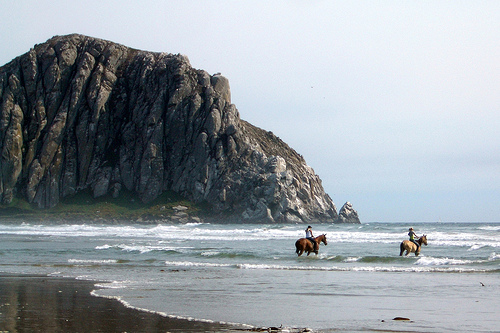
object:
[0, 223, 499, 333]
ocean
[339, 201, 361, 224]
rocks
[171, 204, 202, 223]
rocks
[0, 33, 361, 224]
rocks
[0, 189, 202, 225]
grass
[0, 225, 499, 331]
waves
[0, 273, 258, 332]
sand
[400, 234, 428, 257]
brown horse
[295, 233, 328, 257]
horse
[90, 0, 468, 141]
cloud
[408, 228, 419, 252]
rider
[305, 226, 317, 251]
man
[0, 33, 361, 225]
hill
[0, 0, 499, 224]
sky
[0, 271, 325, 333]
shore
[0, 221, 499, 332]
beach